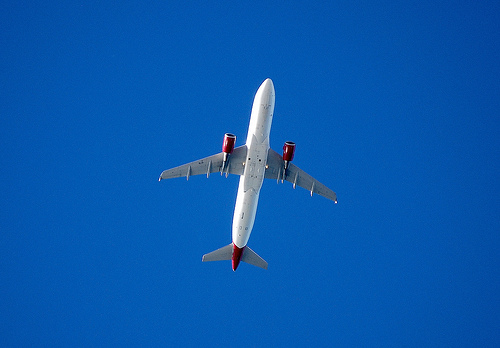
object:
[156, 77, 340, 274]
plane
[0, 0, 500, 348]
sky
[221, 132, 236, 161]
engines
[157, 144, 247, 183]
wings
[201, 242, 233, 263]
tail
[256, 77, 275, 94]
nose